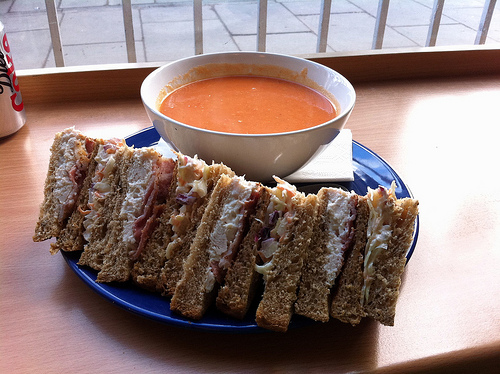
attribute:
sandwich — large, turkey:
[55, 128, 388, 314]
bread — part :
[40, 144, 413, 325]